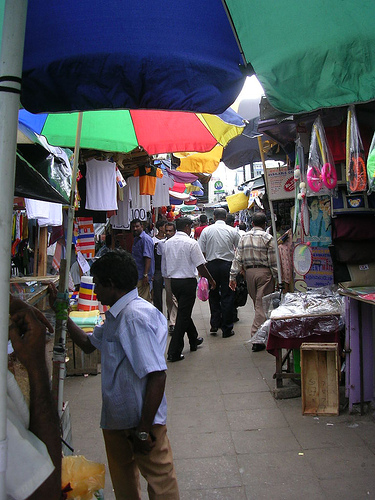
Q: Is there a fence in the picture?
A: No, there are no fences.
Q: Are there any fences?
A: No, there are no fences.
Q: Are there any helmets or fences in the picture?
A: No, there are no fences or helmets.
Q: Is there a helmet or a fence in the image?
A: No, there are no fences or helmets.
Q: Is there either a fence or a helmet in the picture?
A: No, there are no fences or helmets.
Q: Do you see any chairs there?
A: No, there are no chairs.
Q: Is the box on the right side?
A: Yes, the box is on the right of the image.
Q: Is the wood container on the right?
A: Yes, the box is on the right of the image.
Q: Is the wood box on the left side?
A: No, the box is on the right of the image.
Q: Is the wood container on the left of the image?
A: No, the box is on the right of the image.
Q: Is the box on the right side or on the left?
A: The box is on the right of the image.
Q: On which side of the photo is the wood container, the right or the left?
A: The box is on the right of the image.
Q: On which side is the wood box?
A: The box is on the right of the image.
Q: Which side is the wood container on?
A: The box is on the right of the image.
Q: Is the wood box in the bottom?
A: Yes, the box is in the bottom of the image.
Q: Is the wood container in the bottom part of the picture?
A: Yes, the box is in the bottom of the image.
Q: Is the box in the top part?
A: No, the box is in the bottom of the image.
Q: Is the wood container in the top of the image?
A: No, the box is in the bottom of the image.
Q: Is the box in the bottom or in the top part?
A: The box is in the bottom of the image.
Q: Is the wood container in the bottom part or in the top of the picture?
A: The box is in the bottom of the image.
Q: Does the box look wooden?
A: Yes, the box is wooden.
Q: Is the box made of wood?
A: Yes, the box is made of wood.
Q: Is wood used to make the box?
A: Yes, the box is made of wood.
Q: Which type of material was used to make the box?
A: The box is made of wood.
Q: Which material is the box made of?
A: The box is made of wood.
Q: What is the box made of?
A: The box is made of wood.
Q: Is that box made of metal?
A: No, the box is made of wood.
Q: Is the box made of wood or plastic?
A: The box is made of wood.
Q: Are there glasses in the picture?
A: No, there are no glasses.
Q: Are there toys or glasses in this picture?
A: No, there are no glasses or toys.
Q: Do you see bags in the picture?
A: Yes, there is a bag.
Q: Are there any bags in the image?
A: Yes, there is a bag.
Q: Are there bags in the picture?
A: Yes, there is a bag.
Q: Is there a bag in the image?
A: Yes, there is a bag.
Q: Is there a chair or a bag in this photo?
A: Yes, there is a bag.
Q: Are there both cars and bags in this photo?
A: No, there is a bag but no cars.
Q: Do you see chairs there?
A: No, there are no chairs.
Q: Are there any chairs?
A: No, there are no chairs.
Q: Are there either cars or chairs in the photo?
A: No, there are no chairs or cars.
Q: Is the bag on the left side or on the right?
A: The bag is on the left of the image.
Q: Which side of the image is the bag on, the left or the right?
A: The bag is on the left of the image.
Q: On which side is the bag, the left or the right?
A: The bag is on the left of the image.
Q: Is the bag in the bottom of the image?
A: Yes, the bag is in the bottom of the image.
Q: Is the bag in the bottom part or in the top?
A: The bag is in the bottom of the image.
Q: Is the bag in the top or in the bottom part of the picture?
A: The bag is in the bottom of the image.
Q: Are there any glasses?
A: No, there are no glasses.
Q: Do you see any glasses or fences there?
A: No, there are no glasses or fences.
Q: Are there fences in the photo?
A: No, there are no fences.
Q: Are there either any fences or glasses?
A: No, there are no fences or glasses.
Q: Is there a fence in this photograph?
A: No, there are no fences.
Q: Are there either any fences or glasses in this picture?
A: No, there are no fences or glasses.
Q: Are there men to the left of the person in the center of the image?
A: Yes, there is a man to the left of the person.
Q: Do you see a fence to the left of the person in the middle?
A: No, there is a man to the left of the person.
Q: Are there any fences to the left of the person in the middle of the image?
A: No, there is a man to the left of the person.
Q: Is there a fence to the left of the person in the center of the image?
A: No, there is a man to the left of the person.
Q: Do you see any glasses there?
A: No, there are no glasses.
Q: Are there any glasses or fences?
A: No, there are no glasses or fences.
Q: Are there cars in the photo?
A: No, there are no cars.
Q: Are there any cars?
A: No, there are no cars.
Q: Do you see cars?
A: No, there are no cars.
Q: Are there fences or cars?
A: No, there are no cars or fences.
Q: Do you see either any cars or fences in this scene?
A: No, there are no cars or fences.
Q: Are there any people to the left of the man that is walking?
A: Yes, there is a person to the left of the man.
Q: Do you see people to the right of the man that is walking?
A: No, the person is to the left of the man.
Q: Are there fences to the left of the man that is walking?
A: No, there is a person to the left of the man.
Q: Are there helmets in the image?
A: No, there are no helmets.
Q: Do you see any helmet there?
A: No, there are no helmets.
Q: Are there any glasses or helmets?
A: No, there are no helmets or glasses.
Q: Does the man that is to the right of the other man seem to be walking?
A: Yes, the man is walking.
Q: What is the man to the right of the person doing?
A: The man is walking.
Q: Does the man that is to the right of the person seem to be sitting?
A: No, the man is walking.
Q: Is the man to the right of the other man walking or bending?
A: The man is walking.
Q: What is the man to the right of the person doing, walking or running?
A: The man is walking.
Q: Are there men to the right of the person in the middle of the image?
A: Yes, there is a man to the right of the person.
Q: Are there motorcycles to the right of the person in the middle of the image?
A: No, there is a man to the right of the person.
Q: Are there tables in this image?
A: Yes, there is a table.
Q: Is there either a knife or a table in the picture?
A: Yes, there is a table.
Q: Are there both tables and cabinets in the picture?
A: No, there is a table but no cabinets.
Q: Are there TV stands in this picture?
A: No, there are no TV stands.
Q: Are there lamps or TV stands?
A: No, there are no TV stands or lamps.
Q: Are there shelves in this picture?
A: No, there are no shelves.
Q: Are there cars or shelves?
A: No, there are no shelves or cars.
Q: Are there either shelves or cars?
A: No, there are no shelves or cars.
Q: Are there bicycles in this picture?
A: No, there are no bicycles.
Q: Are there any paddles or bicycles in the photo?
A: No, there are no bicycles or paddles.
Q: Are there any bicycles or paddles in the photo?
A: No, there are no bicycles or paddles.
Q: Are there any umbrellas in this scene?
A: Yes, there is an umbrella.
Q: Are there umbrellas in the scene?
A: Yes, there is an umbrella.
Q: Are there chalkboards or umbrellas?
A: Yes, there is an umbrella.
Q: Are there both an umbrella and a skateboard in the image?
A: No, there is an umbrella but no skateboards.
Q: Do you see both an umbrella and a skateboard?
A: No, there is an umbrella but no skateboards.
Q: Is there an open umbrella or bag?
A: Yes, there is an open umbrella.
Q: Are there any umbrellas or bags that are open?
A: Yes, the umbrella is open.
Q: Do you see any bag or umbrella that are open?
A: Yes, the umbrella is open.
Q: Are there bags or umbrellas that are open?
A: Yes, the umbrella is open.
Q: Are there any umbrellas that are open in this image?
A: Yes, there is an open umbrella.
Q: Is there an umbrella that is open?
A: Yes, there is an umbrella that is open.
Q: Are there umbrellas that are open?
A: Yes, there is an umbrella that is open.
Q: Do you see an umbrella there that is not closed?
A: Yes, there is a open umbrella.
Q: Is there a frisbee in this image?
A: No, there are no frisbees.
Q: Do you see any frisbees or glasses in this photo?
A: No, there are no frisbees or glasses.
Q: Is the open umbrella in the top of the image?
A: Yes, the umbrella is in the top of the image.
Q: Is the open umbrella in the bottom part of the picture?
A: No, the umbrella is in the top of the image.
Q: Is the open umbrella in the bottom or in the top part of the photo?
A: The umbrella is in the top of the image.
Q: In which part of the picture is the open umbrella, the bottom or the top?
A: The umbrella is in the top of the image.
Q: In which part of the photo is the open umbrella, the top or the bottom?
A: The umbrella is in the top of the image.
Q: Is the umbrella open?
A: Yes, the umbrella is open.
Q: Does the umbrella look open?
A: Yes, the umbrella is open.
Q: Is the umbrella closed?
A: No, the umbrella is open.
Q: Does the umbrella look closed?
A: No, the umbrella is open.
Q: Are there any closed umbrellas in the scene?
A: No, there is an umbrella but it is open.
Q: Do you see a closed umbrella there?
A: No, there is an umbrella but it is open.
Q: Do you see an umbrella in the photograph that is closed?
A: No, there is an umbrella but it is open.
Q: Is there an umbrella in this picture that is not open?
A: No, there is an umbrella but it is open.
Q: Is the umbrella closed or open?
A: The umbrella is open.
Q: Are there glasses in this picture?
A: No, there are no glasses.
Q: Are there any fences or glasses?
A: No, there are no glasses or fences.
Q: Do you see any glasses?
A: No, there are no glasses.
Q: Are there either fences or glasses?
A: No, there are no glasses or fences.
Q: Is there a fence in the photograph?
A: No, there are no fences.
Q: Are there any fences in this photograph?
A: No, there are no fences.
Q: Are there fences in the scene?
A: No, there are no fences.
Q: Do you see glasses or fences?
A: No, there are no fences or glasses.